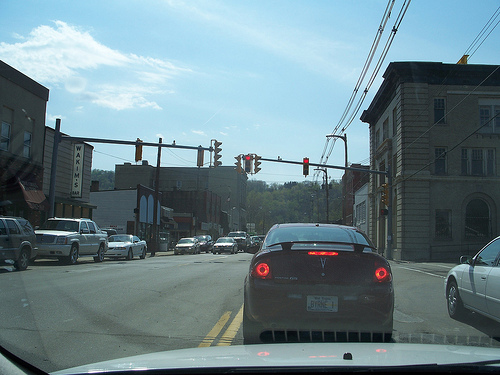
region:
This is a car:
[233, 209, 413, 353]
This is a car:
[174, 228, 206, 262]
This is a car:
[192, 226, 214, 253]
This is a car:
[212, 231, 240, 253]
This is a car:
[229, 225, 251, 245]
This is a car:
[106, 225, 148, 263]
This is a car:
[33, 205, 112, 272]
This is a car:
[0, 200, 42, 276]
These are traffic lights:
[296, 148, 323, 198]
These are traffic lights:
[239, 142, 270, 194]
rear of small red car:
[238, 216, 399, 341]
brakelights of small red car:
[251, 250, 393, 286]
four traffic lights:
[131, 134, 311, 178]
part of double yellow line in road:
[193, 302, 247, 350]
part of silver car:
[441, 233, 498, 325]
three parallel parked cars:
[1, 212, 151, 270]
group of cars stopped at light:
[211, 227, 266, 254]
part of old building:
[358, 56, 497, 261]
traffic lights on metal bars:
[41, 111, 398, 268]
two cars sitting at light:
[241, 218, 498, 340]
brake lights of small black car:
[262, 271, 397, 309]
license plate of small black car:
[300, 288, 352, 344]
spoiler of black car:
[260, 223, 392, 291]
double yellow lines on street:
[185, 335, 250, 348]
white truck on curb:
[50, 222, 98, 267]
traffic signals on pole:
[235, 146, 330, 194]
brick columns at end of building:
[389, 216, 428, 268]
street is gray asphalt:
[82, 292, 124, 336]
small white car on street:
[114, 233, 163, 293]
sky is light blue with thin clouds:
[232, 84, 271, 141]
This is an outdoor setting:
[11, 48, 475, 356]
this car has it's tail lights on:
[229, 219, 398, 327]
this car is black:
[246, 222, 438, 370]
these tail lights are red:
[246, 262, 278, 281]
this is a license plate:
[287, 285, 359, 321]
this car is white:
[439, 253, 489, 289]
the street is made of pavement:
[72, 263, 187, 327]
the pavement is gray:
[48, 297, 175, 333]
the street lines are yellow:
[193, 303, 278, 373]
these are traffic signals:
[213, 140, 399, 196]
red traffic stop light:
[302, 153, 309, 180]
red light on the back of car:
[245, 258, 272, 285]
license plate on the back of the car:
[298, 290, 343, 316]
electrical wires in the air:
[343, 84, 362, 119]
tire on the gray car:
[441, 270, 458, 315]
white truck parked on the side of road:
[37, 214, 107, 260]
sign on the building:
[70, 143, 82, 203]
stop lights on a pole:
[207, 135, 222, 172]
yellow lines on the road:
[206, 302, 237, 343]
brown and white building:
[105, 185, 157, 235]